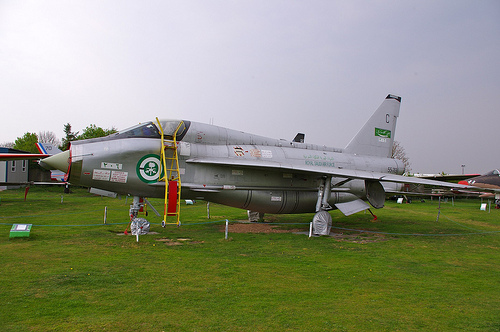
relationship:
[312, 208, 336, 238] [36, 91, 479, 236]
landing gear on jet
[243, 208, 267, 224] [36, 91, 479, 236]
landing gear on jet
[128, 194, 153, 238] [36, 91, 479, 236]
landing gear on jet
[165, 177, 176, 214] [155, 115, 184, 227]
panel behind ladder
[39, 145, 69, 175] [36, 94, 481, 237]
nose on airplane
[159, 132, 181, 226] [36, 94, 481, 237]
ladder coming off airplane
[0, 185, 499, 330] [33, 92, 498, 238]
grass in front of airplane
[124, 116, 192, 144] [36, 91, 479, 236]
cockpit belonging to jet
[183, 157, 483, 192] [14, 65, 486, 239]
wing of jet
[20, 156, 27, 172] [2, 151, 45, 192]
window on house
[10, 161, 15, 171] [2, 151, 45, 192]
window on house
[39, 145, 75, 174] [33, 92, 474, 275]
nose of plane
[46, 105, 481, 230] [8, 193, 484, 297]
airplane sitting on grass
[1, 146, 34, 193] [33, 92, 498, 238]
house behind airplane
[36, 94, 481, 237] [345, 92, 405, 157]
airplane has tail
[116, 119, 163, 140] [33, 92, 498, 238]
window on airplane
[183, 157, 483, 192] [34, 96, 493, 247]
wing of plane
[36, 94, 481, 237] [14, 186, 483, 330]
airplane on ground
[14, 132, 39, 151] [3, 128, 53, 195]
leaves on tree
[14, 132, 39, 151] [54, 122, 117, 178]
leaves on tree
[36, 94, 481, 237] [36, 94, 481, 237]
airplane has airplane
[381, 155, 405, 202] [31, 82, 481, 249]
thrusts of jet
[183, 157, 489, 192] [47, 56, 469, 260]
wing of plane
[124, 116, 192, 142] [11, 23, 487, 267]
cockpit of plane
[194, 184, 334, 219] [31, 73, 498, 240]
underbelly of plane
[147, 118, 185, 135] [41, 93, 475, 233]
windshield of airplane